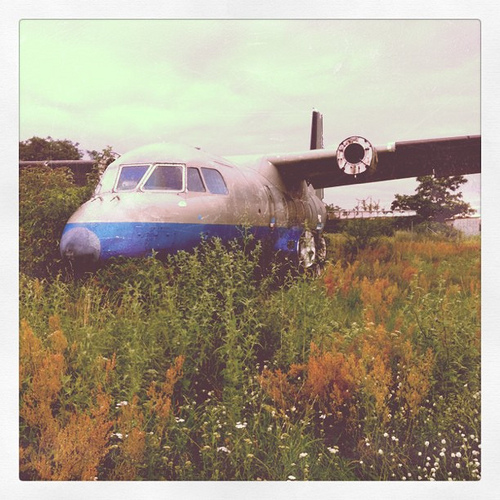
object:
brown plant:
[307, 340, 363, 421]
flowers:
[439, 452, 445, 457]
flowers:
[451, 453, 455, 458]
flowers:
[422, 467, 427, 472]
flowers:
[475, 462, 481, 468]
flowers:
[235, 421, 248, 429]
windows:
[271, 190, 323, 219]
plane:
[19, 110, 482, 268]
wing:
[268, 134, 481, 190]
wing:
[19, 160, 109, 166]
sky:
[19, 18, 481, 211]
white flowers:
[456, 462, 461, 468]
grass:
[18, 233, 480, 482]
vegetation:
[20, 242, 483, 483]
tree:
[390, 174, 476, 222]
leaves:
[390, 175, 477, 219]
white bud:
[327, 445, 339, 453]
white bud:
[391, 436, 399, 442]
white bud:
[299, 452, 308, 459]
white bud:
[217, 446, 231, 454]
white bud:
[175, 417, 185, 423]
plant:
[19, 136, 482, 482]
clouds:
[19, 19, 479, 154]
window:
[143, 166, 183, 191]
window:
[187, 166, 230, 195]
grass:
[17, 247, 274, 409]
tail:
[310, 110, 324, 200]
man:
[20, 104, 380, 286]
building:
[327, 210, 481, 237]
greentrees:
[19, 135, 116, 277]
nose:
[59, 227, 101, 269]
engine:
[335, 136, 378, 180]